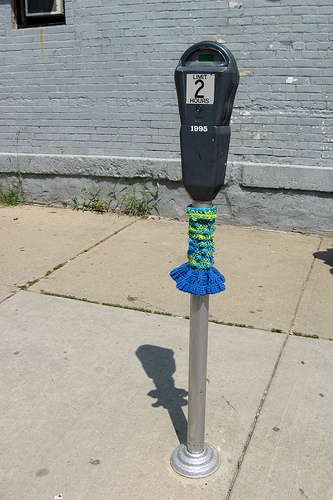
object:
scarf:
[169, 204, 226, 296]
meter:
[170, 40, 241, 479]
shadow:
[135, 344, 189, 445]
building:
[0, 0, 332, 237]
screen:
[199, 51, 213, 61]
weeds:
[0, 179, 160, 219]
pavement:
[0, 204, 333, 500]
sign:
[186, 73, 216, 105]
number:
[191, 126, 208, 132]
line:
[3, 286, 330, 347]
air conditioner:
[25, 1, 63, 16]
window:
[12, 1, 66, 30]